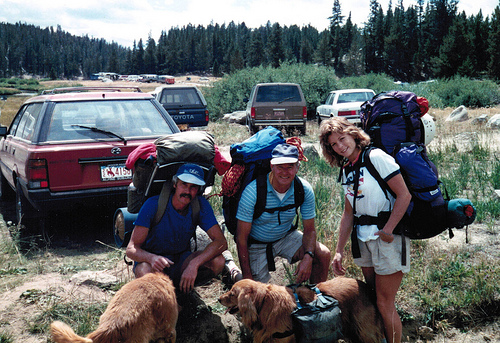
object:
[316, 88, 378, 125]
car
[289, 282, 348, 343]
bag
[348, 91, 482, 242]
backpack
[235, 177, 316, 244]
shirt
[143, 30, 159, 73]
pine tree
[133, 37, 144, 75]
pine tree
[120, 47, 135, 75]
pine tree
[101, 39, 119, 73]
pine tree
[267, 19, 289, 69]
pine tree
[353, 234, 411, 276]
shorts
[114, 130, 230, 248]
camping gear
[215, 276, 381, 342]
dog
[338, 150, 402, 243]
shirt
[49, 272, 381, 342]
dogs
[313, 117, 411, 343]
lady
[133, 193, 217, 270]
shirt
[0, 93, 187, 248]
car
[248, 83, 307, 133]
van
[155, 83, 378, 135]
vehicles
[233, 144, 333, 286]
backpacker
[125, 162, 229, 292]
backpacker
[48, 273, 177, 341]
dog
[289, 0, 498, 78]
trees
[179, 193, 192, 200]
moustache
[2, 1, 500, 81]
forest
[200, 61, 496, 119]
shrubbery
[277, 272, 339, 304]
back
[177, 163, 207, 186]
cap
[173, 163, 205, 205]
head